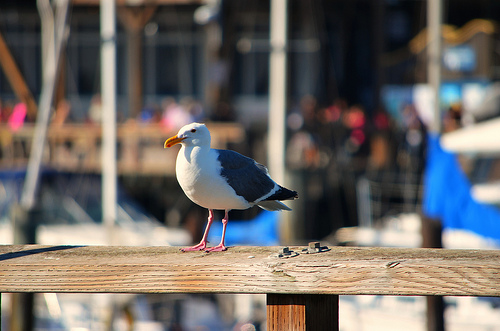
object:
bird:
[162, 120, 298, 253]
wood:
[4, 243, 499, 295]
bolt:
[275, 246, 300, 259]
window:
[144, 39, 199, 97]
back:
[4, 6, 494, 245]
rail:
[0, 243, 500, 331]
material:
[422, 135, 498, 240]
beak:
[164, 135, 187, 149]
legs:
[221, 210, 230, 243]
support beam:
[3, 0, 129, 246]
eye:
[190, 129, 196, 133]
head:
[163, 121, 211, 149]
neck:
[175, 141, 212, 150]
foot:
[179, 238, 211, 252]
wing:
[217, 152, 302, 207]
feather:
[243, 170, 264, 186]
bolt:
[300, 241, 331, 254]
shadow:
[298, 292, 341, 325]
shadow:
[193, 131, 303, 229]